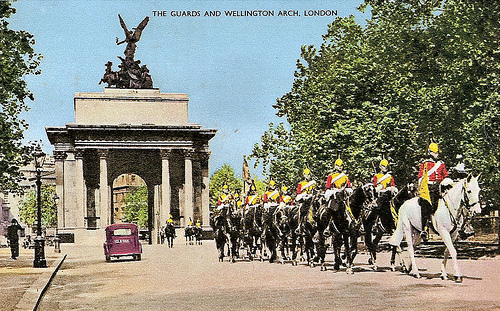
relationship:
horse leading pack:
[390, 167, 486, 289] [210, 141, 485, 280]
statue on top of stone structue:
[93, 6, 161, 91] [34, 80, 249, 260]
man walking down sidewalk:
[2, 217, 28, 260] [0, 243, 69, 309]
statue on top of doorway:
[97, 14, 160, 92] [44, 122, 223, 245]